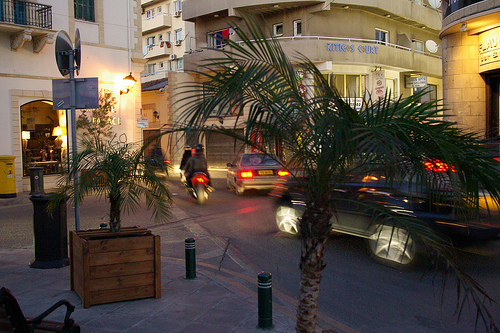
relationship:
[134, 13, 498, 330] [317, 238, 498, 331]
palm tree on road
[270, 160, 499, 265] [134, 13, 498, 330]
car behind palm tree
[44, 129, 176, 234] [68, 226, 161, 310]
tree inside of crate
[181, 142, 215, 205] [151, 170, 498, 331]
motorcycle going down road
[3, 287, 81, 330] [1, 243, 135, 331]
bench on sidewalk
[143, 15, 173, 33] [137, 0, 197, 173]
balcony on building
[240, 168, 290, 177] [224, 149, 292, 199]
tail lights on car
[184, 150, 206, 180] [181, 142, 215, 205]
man on motorcycle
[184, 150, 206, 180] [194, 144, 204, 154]
man wears helmet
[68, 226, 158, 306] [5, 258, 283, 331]
crate on sidewalk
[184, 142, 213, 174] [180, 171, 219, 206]
man on motorcycle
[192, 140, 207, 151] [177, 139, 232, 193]
helmet on man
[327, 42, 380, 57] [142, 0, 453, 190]
writing on building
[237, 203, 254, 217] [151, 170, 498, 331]
red reflection on road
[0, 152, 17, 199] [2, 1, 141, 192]
trash can near building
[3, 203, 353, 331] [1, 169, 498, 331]
floor has concrete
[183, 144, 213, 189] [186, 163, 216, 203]
man has motorcycle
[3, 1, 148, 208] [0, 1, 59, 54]
building has balcony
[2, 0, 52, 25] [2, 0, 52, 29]
balcony has railing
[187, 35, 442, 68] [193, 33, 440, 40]
balcony has railing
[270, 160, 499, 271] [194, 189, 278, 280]
car on road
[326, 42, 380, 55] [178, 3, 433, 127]
writing on building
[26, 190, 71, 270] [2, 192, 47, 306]
waste bin on sidewalk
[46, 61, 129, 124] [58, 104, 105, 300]
sign on pole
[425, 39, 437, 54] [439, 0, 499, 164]
dish on building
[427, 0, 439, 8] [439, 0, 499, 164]
dish on building